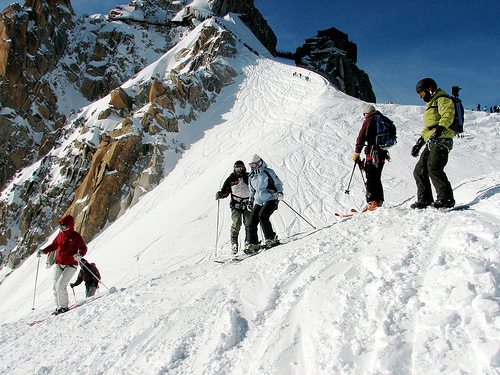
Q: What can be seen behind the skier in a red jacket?
A: A mountain peak with rocks and snow.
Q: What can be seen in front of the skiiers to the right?
A: Snow with tracks.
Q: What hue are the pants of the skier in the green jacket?
A: Black.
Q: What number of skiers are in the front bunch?
A: Five.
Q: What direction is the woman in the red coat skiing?
A: Downward.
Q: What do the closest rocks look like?
A: They are covered in snow.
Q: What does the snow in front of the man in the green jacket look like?
A: It is broken up.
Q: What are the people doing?
A: They are skiing.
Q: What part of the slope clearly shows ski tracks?
A: The area between skier number three and four.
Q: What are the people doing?
A: Skiing.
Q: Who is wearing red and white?
A: The woman on the left.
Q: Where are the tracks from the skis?
A: In the snow.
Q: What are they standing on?
A: The snow.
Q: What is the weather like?
A: Sunny and cold.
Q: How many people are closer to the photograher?
A: 5 people near the photograher.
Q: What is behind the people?
A: There are mountains.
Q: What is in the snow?
A: There are lines in the snow.